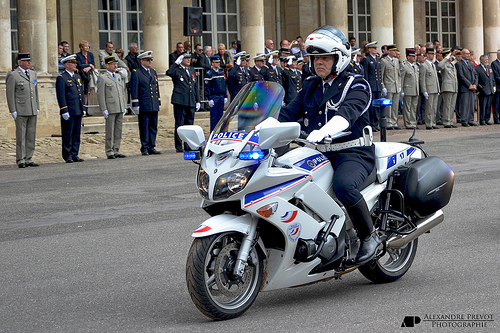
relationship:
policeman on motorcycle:
[272, 27, 389, 269] [173, 81, 451, 322]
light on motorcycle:
[239, 150, 266, 160] [173, 81, 451, 322]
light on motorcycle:
[178, 145, 200, 168] [173, 81, 451, 322]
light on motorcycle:
[363, 95, 399, 111] [173, 81, 451, 322]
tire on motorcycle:
[168, 208, 279, 330] [173, 81, 451, 322]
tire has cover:
[168, 208, 279, 330] [185, 198, 283, 261]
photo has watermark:
[1, 1, 499, 333] [392, 308, 499, 332]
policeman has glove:
[272, 27, 389, 269] [299, 112, 352, 152]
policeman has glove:
[272, 27, 389, 269] [246, 111, 279, 138]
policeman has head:
[272, 27, 389, 269] [305, 45, 351, 81]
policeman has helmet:
[272, 27, 389, 269] [303, 25, 352, 81]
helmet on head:
[303, 25, 352, 81] [305, 45, 351, 81]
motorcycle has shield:
[173, 81, 451, 322] [196, 72, 288, 162]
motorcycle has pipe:
[173, 81, 451, 322] [385, 205, 442, 249]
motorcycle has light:
[173, 81, 451, 322] [239, 150, 266, 160]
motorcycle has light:
[173, 81, 451, 322] [178, 145, 200, 168]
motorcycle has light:
[173, 81, 451, 322] [363, 95, 399, 111]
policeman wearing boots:
[272, 27, 389, 269] [335, 191, 388, 276]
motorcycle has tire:
[173, 81, 451, 322] [168, 208, 279, 330]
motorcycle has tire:
[173, 81, 451, 322] [347, 205, 425, 287]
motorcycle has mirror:
[173, 81, 451, 322] [171, 117, 209, 159]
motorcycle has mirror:
[173, 81, 451, 322] [244, 113, 307, 159]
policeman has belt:
[272, 27, 389, 269] [300, 123, 379, 161]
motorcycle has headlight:
[173, 81, 451, 322] [215, 163, 260, 205]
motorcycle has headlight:
[173, 81, 451, 322] [190, 161, 212, 203]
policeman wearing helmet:
[273, 23, 386, 266] [304, 27, 358, 74]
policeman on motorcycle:
[273, 23, 386, 266] [173, 81, 451, 322]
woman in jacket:
[76, 39, 94, 116] [76, 51, 96, 71]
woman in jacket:
[76, 39, 94, 116] [76, 44, 97, 78]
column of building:
[138, 1, 172, 78] [1, 1, 498, 129]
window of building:
[99, 1, 146, 58] [1, 1, 498, 129]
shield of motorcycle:
[206, 78, 285, 149] [173, 81, 451, 322]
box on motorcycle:
[390, 151, 457, 220] [173, 81, 451, 322]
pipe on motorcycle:
[385, 205, 442, 249] [173, 81, 451, 322]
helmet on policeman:
[305, 27, 351, 78] [280, 27, 385, 265]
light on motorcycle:
[236, 149, 262, 160] [173, 81, 451, 322]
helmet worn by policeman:
[303, 25, 352, 81] [273, 23, 386, 266]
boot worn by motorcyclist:
[345, 195, 389, 267] [280, 27, 391, 269]